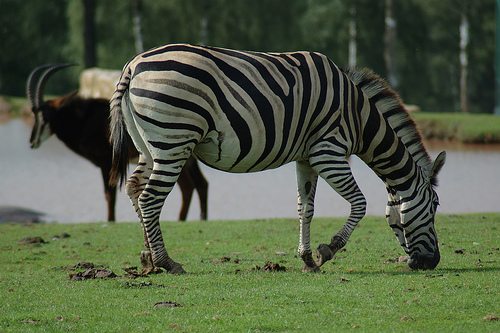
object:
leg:
[295, 162, 323, 272]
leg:
[308, 146, 369, 268]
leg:
[137, 158, 187, 276]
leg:
[127, 159, 165, 276]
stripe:
[151, 167, 181, 178]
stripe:
[148, 178, 178, 190]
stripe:
[154, 155, 192, 166]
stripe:
[146, 135, 200, 150]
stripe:
[128, 105, 204, 138]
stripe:
[127, 112, 210, 135]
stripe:
[135, 59, 252, 173]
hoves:
[292, 241, 340, 270]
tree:
[453, 0, 474, 115]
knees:
[199, 178, 208, 197]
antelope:
[18, 58, 230, 220]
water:
[0, 95, 500, 217]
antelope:
[21, 59, 211, 221]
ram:
[21, 56, 225, 247]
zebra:
[107, 44, 446, 276]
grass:
[3, 212, 499, 330]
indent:
[152, 300, 180, 311]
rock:
[74, 69, 116, 91]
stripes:
[209, 57, 294, 127]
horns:
[22, 56, 79, 113]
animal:
[29, 73, 144, 180]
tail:
[108, 72, 129, 184]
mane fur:
[341, 61, 438, 185]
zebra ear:
[433, 150, 449, 182]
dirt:
[62, 257, 117, 284]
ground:
[7, 225, 497, 331]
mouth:
[409, 252, 442, 271]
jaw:
[380, 181, 437, 274]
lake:
[2, 111, 498, 229]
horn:
[32, 63, 67, 106]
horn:
[17, 55, 42, 105]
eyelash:
[436, 202, 442, 206]